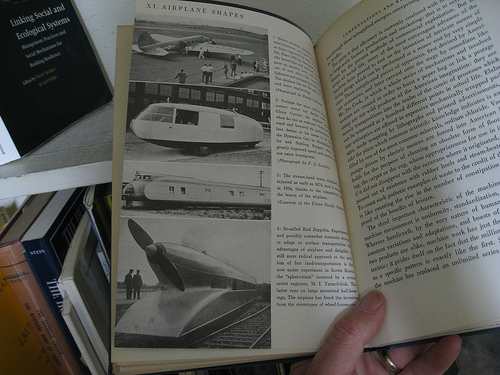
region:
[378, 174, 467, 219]
black words on page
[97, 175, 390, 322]
white pages in book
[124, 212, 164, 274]
black propeller on plane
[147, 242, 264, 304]
large silver plane in book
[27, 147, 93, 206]
white edge of surface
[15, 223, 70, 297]
binder of black book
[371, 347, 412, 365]
gold ring on person's finger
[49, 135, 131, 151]
white surface on table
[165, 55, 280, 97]
people walking on sidewalk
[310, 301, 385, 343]
grooves in person's finger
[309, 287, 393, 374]
Thumb at the bottom of a book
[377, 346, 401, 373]
Ring on a hand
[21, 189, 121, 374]
Black book standing vertically on bottom shelf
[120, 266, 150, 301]
Men standing next to a plane in bottom picture in open book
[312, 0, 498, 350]
Printed unillustrated page of a book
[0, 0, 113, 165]
Black book standing on top shelf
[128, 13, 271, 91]
Top picture on page of open book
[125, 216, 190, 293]
Propeller on plane in bottom picture in open book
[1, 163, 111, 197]
Front of white shelf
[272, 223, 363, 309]
Last paragraph on page of open book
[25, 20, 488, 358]
open book in front of shelves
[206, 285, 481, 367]
thumb and fingers holding book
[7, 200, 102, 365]
hard cover and soft covers books on shelf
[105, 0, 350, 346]
photographs and text on same page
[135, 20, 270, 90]
people on ramp looking at airplane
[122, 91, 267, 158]
broad and curved vehicle with windows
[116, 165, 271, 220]
vehicle with airplane nose and train body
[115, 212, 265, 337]
propeller at end of bisected train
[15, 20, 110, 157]
empty space in front of a black book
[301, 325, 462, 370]
gold ring on finger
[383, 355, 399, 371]
this is a ring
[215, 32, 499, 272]
this is a book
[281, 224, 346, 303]
these are the writings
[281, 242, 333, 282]
the writings are in black in color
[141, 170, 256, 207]
this is a train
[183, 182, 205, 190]
the train is white in color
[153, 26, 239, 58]
this is a jet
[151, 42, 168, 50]
the jet is white in color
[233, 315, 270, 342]
this is a railway line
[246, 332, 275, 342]
this is a metal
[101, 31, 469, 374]
person reading a book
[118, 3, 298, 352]
different types of airplanes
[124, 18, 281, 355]
black and white photographs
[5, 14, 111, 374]
books on a shelf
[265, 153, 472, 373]
married person holding a book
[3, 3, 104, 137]
book on social and economic systems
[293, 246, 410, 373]
person's dirty thumb nail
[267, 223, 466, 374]
caucasian person holding an open book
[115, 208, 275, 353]
airplane on train tracks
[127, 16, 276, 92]
older airplane pictured with spectators